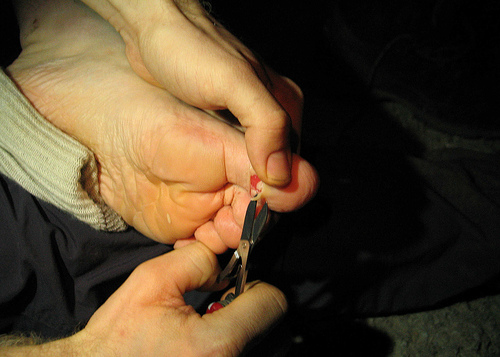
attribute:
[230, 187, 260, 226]
toe — smaller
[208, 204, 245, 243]
toe — smaller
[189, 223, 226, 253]
toe — smaller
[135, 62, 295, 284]
foot — white, pale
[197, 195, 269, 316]
metal instrument — metal 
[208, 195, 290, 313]
scissors — small , black , stainless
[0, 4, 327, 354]
skin — open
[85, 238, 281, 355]
hand — human 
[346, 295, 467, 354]
carpet — gray, soft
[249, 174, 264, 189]
hole — red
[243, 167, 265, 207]
wound — open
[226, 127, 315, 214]
toe — big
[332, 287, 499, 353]
carpet — grey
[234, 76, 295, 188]
thumb — left-hand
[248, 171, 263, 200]
skin — missing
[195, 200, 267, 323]
scissors — small 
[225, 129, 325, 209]
toe — big 